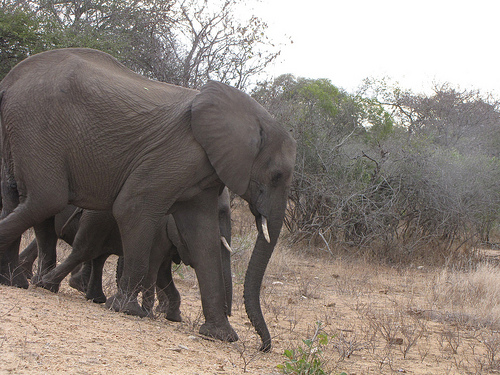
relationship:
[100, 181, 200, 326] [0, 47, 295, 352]
leg of elephant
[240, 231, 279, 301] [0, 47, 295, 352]
trunk of elephant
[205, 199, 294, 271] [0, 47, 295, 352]
tusk on elephant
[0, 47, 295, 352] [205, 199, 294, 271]
elephant has tusk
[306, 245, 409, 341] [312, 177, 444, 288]
grass has no leaves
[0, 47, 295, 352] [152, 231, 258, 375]
elephant has feet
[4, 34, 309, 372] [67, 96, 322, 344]
elephant walking down hill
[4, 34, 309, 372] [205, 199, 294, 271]
elephant has tusk